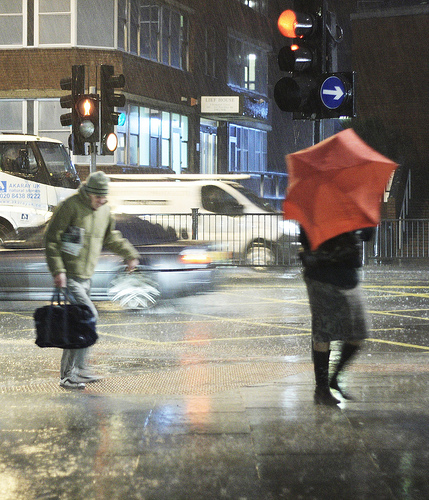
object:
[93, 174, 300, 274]
van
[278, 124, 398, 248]
umbrella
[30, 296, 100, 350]
canvas briefcase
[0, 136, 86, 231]
truck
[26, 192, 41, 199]
words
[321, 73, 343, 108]
directional light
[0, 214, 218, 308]
car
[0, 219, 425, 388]
street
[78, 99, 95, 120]
signal light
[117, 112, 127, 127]
signal light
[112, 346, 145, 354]
rain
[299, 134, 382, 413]
woman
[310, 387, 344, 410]
boots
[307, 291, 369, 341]
skirt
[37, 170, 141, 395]
man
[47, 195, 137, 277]
jacket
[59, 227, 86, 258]
newspaper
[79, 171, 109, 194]
cap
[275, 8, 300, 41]
traffic signal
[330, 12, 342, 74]
pole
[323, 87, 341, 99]
arrow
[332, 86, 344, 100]
right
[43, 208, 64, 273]
arm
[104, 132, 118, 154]
traffic light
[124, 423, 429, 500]
road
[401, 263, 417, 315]
rain drops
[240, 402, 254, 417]
ground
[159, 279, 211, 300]
shadow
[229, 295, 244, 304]
light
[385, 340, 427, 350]
lines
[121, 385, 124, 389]
grates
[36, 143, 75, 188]
window